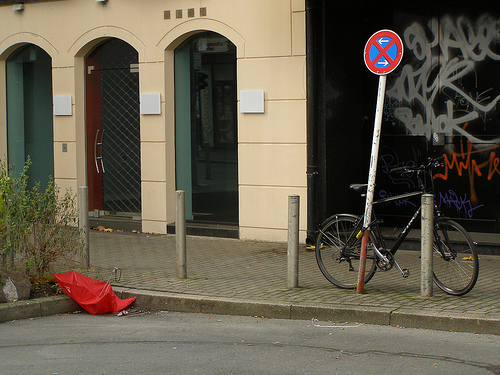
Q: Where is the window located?
A: In the archway.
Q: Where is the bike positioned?
A: Under the sign.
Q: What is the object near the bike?
A: A grey brick sidewalk.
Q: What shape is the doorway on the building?
A: Arched.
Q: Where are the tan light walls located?
A: On the building.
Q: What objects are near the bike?
A: Metal poles.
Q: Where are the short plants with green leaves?
A: Near the umbrella.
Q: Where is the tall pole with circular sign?
A: Near the bike.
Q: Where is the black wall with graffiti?
A: On the building.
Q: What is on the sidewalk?
A: Black bike.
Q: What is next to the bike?
A: Metal poles.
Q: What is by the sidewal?
A: Gray brick.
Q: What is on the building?
A: Front door.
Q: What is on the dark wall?
A: White graffiti.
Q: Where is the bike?
A: Resting on a pole.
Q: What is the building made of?
A: Stone.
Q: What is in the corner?
A: A red bag.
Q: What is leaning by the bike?
A: A street sign.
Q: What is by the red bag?
A: A bush.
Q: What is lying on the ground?
A: A broken red umbrella.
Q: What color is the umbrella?
A: Red.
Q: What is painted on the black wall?
A: Graffiti.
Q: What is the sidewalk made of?
A: Bricks.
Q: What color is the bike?
A: Black.